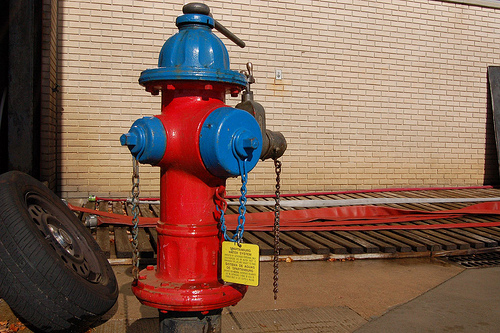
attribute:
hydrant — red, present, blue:
[119, 2, 288, 333]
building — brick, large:
[0, 0, 499, 195]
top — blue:
[137, 3, 255, 84]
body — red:
[130, 81, 248, 314]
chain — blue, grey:
[218, 176, 248, 245]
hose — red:
[67, 202, 497, 231]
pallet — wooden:
[80, 185, 499, 260]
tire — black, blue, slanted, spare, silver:
[0, 168, 121, 333]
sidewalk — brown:
[89, 262, 497, 330]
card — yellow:
[221, 241, 260, 288]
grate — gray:
[450, 250, 499, 269]